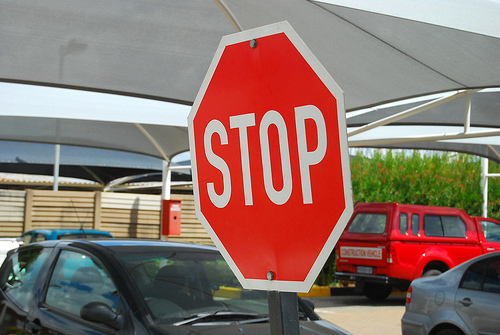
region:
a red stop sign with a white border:
[187, 18, 355, 293]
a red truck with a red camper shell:
[329, 200, 499, 302]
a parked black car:
[1, 234, 348, 333]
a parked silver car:
[401, 248, 499, 333]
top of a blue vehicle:
[15, 228, 115, 240]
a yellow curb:
[215, 283, 331, 301]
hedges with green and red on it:
[315, 149, 495, 286]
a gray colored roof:
[2, 1, 499, 145]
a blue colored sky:
[324, 0, 498, 37]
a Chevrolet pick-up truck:
[339, 199, 496, 298]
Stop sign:
[180, 25, 352, 294]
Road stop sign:
[184, 16, 356, 298]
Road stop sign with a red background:
[186, 13, 363, 307]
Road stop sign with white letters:
[180, 23, 366, 303]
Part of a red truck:
[355, 188, 495, 282]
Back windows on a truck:
[392, 205, 481, 245]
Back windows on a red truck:
[347, 201, 476, 251]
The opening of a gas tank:
[427, 287, 451, 308]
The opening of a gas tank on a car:
[430, 289, 448, 311]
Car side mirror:
[71, 297, 137, 333]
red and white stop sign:
[192, 19, 374, 296]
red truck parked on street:
[330, 192, 491, 289]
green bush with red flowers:
[345, 150, 487, 206]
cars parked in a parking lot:
[7, 185, 485, 330]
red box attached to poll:
[154, 191, 186, 243]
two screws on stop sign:
[242, 28, 281, 288]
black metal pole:
[257, 280, 306, 332]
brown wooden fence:
[2, 189, 226, 240]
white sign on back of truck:
[330, 240, 392, 261]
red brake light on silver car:
[400, 278, 422, 313]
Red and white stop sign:
[191, 13, 358, 300]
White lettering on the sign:
[197, 92, 337, 207]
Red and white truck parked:
[338, 193, 497, 303]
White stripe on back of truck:
[335, 236, 392, 272]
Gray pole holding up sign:
[257, 282, 295, 331]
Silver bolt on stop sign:
[262, 268, 282, 282]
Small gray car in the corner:
[400, 225, 498, 334]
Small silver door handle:
[457, 293, 474, 310]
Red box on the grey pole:
[157, 188, 191, 248]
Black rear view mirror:
[77, 295, 127, 327]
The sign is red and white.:
[175, 15, 362, 302]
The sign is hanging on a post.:
[178, 15, 355, 332]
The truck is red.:
[328, 188, 498, 310]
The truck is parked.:
[331, 195, 498, 303]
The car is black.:
[1, 233, 352, 334]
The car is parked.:
[0, 230, 347, 333]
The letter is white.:
[199, 118, 233, 215]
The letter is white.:
[226, 105, 258, 212]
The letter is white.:
[258, 108, 293, 214]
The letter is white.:
[291, 99, 330, 211]